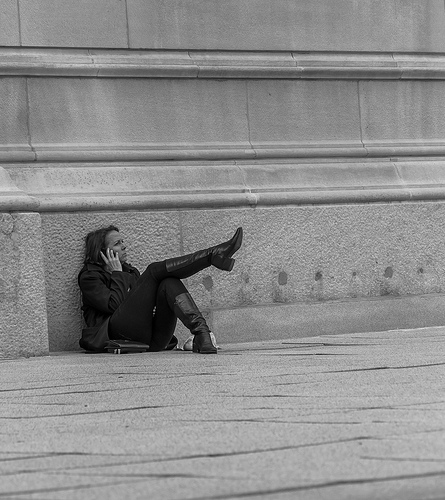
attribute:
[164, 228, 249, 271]
boots — long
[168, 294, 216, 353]
boots —  dark,  long 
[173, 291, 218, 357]
boot — black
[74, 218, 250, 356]
person — using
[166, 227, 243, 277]
boots — tall, black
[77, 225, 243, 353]
person — wearing,  dark, talking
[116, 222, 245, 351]
legs — woman's, folded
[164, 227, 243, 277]
boot — black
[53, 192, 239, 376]
person —  taking 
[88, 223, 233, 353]
female — grown